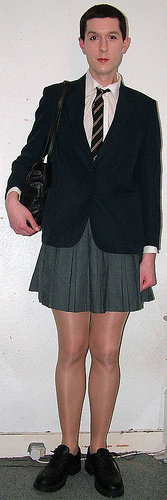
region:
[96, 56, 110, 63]
man wearing red lipstick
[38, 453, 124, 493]
man wearing black shoes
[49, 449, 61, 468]
black shoe strings on sneakers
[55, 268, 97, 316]
man wearing grey skirt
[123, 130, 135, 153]
blue jacket on man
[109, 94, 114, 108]
man wearing white shirt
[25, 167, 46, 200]
black purse on mans shoulders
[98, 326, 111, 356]
man wearing beige stockings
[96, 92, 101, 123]
man wearing black tie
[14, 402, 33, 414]
white paint on walls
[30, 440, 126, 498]
Black shoes.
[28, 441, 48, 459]
A wall outlett with something plugged in.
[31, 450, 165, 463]
The cord that is plugged into the wall.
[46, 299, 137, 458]
This person's legs in stalkings.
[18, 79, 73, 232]
A black purse.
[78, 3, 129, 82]
A person's face.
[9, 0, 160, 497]
The person with short hair.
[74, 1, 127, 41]
Short brown hair.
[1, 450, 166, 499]
The carpet on the floor.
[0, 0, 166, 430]
The white wall.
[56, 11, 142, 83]
man wearing lipstick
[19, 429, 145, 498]
man wearing shoes without socks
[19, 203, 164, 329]
man wearing a grey skirt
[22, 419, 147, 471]
electrical power outlet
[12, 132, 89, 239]
hand carrying a black handbag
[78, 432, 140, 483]
black shoes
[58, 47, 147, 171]
man wearing a dress shirt and tie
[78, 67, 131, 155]
a striped tie on a white dress shirt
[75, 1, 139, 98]
a man with close cropped hair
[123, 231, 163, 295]
a clenched fist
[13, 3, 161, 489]
man wearing black dress shoes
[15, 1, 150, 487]
man wearing red lipstick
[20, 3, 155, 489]
man wearing pleated skirt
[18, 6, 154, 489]
man wearing white button down shirt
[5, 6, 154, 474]
man wearing black suit jacket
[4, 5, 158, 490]
man wearing a tie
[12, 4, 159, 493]
man carrying a black purse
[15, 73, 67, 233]
black leather purse with long straps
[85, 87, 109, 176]
black tie with gray stripes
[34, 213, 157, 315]
gray short skirt with pleats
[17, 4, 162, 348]
a man in a skirt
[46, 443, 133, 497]
he is wearing black men's shoes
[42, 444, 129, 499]
the shoes are untied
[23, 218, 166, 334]
the skirt is grey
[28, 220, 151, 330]
the skirt is pleated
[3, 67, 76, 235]
he is carrying a black shoulder purse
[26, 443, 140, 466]
a cord is plugged in the outlet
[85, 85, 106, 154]
his tie is striped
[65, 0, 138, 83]
the man has brown eyes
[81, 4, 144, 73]
he appears to be wearing lipstick